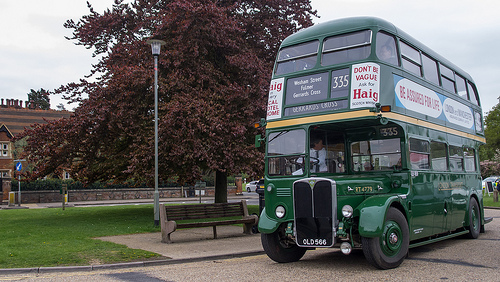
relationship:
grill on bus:
[289, 174, 341, 256] [248, 11, 484, 276]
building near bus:
[5, 98, 76, 182] [218, 1, 499, 266]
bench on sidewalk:
[159, 198, 260, 242] [92, 222, 264, 259]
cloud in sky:
[8, 9, 72, 83] [2, 5, 134, 115]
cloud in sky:
[432, 22, 497, 73] [310, 2, 497, 119]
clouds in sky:
[0, 0, 499, 112] [3, 0, 499, 116]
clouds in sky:
[4, 4, 484, 112] [411, 4, 495, 51]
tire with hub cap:
[346, 204, 434, 271] [381, 220, 403, 251]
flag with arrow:
[12, 160, 30, 175] [14, 164, 22, 169]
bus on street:
[248, 11, 484, 276] [3, 209, 484, 279]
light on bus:
[337, 201, 357, 220] [241, 27, 488, 255]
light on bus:
[269, 204, 288, 216] [241, 27, 488, 255]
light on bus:
[335, 241, 354, 253] [241, 27, 488, 255]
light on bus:
[263, 180, 278, 197] [248, 11, 484, 276]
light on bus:
[335, 204, 356, 218] [248, 11, 484, 276]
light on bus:
[335, 234, 354, 254] [248, 11, 484, 276]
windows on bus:
[289, 32, 396, 72] [268, 19, 470, 257]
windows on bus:
[265, 127, 308, 157] [268, 19, 470, 257]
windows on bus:
[465, 78, 481, 110] [268, 19, 470, 257]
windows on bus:
[456, 70, 468, 96] [268, 19, 470, 257]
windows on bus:
[440, 61, 456, 91] [268, 19, 470, 257]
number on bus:
[331, 74, 351, 89] [248, 11, 484, 276]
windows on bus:
[275, 36, 334, 79] [248, 11, 484, 276]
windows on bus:
[318, 30, 371, 67] [248, 11, 484, 276]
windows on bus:
[375, 28, 400, 72] [248, 11, 484, 276]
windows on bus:
[395, 37, 423, 76] [248, 11, 484, 276]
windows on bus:
[419, 50, 441, 90] [248, 11, 484, 276]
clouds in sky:
[4, 4, 484, 112] [0, 2, 496, 83]